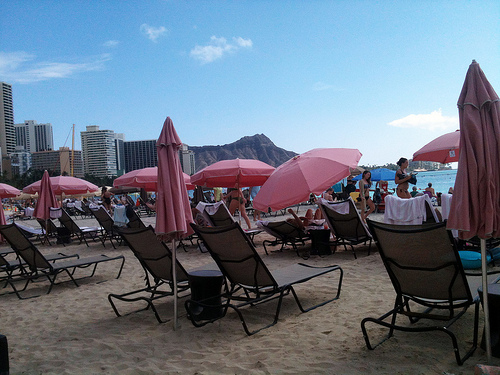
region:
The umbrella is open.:
[18, 166, 105, 241]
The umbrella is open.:
[108, 161, 196, 242]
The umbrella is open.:
[187, 150, 275, 245]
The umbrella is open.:
[249, 137, 369, 265]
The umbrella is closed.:
[29, 158, 73, 262]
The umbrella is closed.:
[138, 110, 214, 345]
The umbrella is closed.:
[431, 45, 498, 372]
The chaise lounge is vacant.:
[1, 217, 129, 297]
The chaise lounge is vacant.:
[194, 212, 347, 347]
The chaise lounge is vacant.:
[332, 206, 499, 356]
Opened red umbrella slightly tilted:
[252, 140, 361, 215]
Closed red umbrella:
[145, 106, 196, 326]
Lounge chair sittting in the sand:
[186, 192, 351, 332]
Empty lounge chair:
[3, 224, 129, 288]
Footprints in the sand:
[104, 343, 264, 369]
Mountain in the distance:
[194, 114, 297, 162]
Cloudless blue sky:
[291, 13, 418, 78]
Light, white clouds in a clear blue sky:
[180, 24, 290, 84]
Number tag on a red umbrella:
[442, 144, 459, 162]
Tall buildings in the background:
[0, 69, 122, 182]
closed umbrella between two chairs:
[151, 115, 198, 332]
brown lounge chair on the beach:
[189, 220, 344, 336]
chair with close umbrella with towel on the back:
[47, 205, 107, 247]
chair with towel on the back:
[317, 197, 373, 255]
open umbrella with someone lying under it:
[252, 145, 362, 223]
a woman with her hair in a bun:
[392, 156, 418, 197]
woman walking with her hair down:
[356, 168, 376, 220]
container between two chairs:
[186, 266, 226, 320]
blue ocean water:
[335, 168, 455, 193]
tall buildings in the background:
[0, 80, 124, 175]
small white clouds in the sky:
[75, 5, 266, 72]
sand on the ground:
[38, 325, 145, 362]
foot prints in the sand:
[269, 335, 327, 355]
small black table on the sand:
[173, 261, 235, 330]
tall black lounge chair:
[198, 214, 350, 337]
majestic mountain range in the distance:
[210, 120, 292, 155]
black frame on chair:
[378, 245, 457, 284]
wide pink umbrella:
[236, 137, 371, 239]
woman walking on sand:
[385, 153, 418, 203]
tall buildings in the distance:
[11, 91, 173, 172]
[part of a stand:
[237, 309, 256, 338]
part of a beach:
[323, 313, 366, 357]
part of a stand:
[236, 303, 284, 356]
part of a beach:
[303, 328, 338, 369]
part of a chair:
[235, 241, 282, 306]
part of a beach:
[311, 295, 336, 336]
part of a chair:
[201, 207, 246, 263]